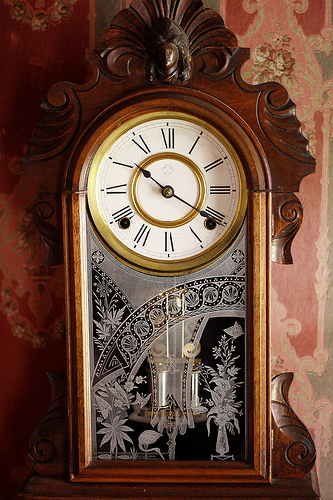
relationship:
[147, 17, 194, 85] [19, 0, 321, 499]
carved face on grandfather clock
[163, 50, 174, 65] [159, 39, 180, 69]
light reflection on carved face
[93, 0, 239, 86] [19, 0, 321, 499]
carving on grandfather clock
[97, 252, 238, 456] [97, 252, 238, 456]
design on design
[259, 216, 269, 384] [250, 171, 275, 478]
light cast on clock frame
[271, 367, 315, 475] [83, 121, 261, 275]
carving on side of clock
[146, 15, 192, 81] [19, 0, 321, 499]
carved head on top of grandfather clock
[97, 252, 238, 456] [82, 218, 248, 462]
design on panel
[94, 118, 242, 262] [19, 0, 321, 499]
face of grandfather clock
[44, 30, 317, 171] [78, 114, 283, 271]
carving around clock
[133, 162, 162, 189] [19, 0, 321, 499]
hand of grandfather clock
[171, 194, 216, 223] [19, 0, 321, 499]
hand of grandfather clock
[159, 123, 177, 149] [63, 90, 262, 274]
number on clock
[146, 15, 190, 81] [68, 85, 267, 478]
carved head on clock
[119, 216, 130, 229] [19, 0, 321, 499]
keyhole on grandfather clock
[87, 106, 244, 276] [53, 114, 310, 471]
frame around clock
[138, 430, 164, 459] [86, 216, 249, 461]
stork etched in glass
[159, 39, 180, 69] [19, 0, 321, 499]
carved face at top of grandfather clock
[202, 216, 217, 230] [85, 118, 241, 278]
keyhole in face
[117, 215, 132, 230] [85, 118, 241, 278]
keyhole in face